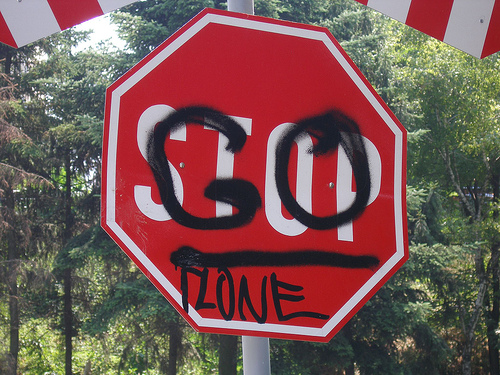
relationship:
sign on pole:
[90, 4, 411, 353] [239, 335, 269, 373]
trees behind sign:
[12, 56, 97, 366] [90, 4, 422, 353]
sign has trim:
[90, 4, 422, 353] [310, 25, 406, 134]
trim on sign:
[201, 11, 330, 47] [90, 4, 422, 353]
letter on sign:
[137, 93, 269, 253] [112, 13, 429, 352]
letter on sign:
[266, 83, 389, 256] [84, 11, 440, 345]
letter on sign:
[171, 264, 214, 323] [112, 13, 429, 352]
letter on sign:
[208, 257, 240, 329] [90, 4, 422, 353]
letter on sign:
[243, 272, 277, 344] [90, 13, 432, 372]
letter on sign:
[270, 268, 328, 345] [90, 4, 422, 353]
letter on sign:
[131, 93, 199, 221] [90, 13, 432, 372]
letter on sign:
[214, 114, 263, 234] [90, 4, 422, 353]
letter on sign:
[327, 127, 381, 245] [90, 13, 432, 372]